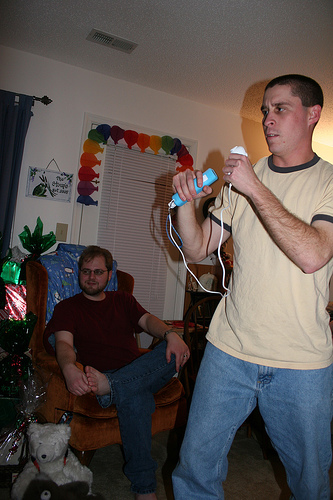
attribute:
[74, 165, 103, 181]
balloon — paper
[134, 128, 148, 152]
balloon — paper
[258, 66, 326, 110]
hair — short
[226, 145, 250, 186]
controller — game, white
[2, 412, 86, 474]
bear — white, teddy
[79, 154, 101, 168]
balloon — paper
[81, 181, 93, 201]
balloon — paper